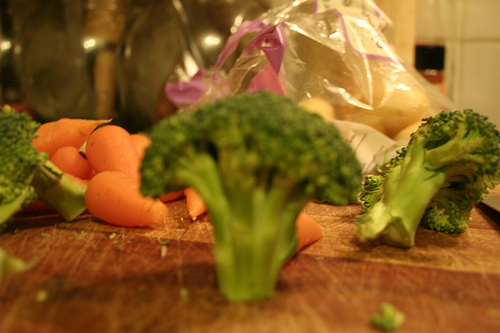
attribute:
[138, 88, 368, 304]
broccoli — green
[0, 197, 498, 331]
table — brown, marked, bronw, wooden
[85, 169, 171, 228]
carrot — orange, stubby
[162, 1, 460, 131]
bag — plastic, pink, clear, white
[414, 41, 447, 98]
bottle — behind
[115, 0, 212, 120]
bowl — silver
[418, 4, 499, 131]
wall — tile